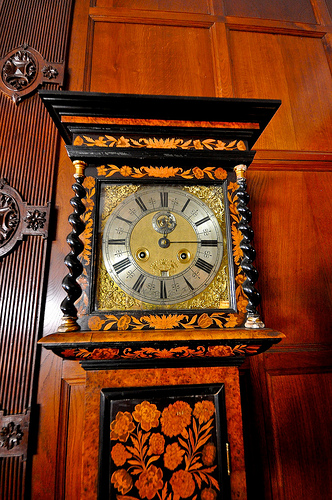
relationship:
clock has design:
[111, 185, 229, 309] [109, 392, 226, 499]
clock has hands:
[111, 185, 229, 309] [169, 223, 212, 260]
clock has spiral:
[111, 185, 229, 309] [51, 197, 95, 303]